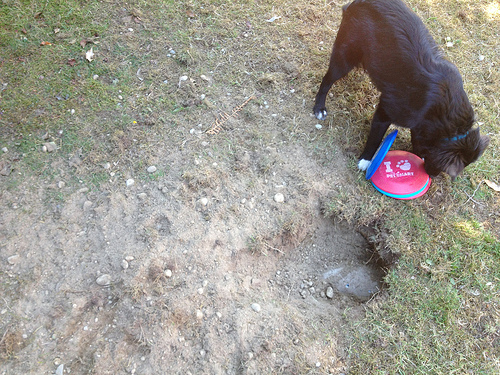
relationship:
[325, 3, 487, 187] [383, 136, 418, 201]
dog playing with kits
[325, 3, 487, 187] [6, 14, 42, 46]
dog on grass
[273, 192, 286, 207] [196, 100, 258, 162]
stone on ground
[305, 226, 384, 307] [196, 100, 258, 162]
hole in ground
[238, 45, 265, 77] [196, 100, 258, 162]
soil on ground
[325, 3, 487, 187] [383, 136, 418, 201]
dog biting kit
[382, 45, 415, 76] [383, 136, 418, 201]
black dog with kit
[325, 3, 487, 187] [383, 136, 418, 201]
dog playing with frisbees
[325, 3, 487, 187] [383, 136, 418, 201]
dog with frisbees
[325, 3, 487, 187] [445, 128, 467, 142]
dog with collar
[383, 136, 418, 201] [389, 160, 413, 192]
frisbees are blue and red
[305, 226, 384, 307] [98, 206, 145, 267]
hole in dirt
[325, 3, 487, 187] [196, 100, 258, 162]
dog has nose in ground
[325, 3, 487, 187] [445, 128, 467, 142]
dog wears collar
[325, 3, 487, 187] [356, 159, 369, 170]
dog has white feet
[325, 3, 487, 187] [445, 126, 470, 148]
dog collar blue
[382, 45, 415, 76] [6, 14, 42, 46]
black dog on grass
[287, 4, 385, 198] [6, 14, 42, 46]
frisbees near grass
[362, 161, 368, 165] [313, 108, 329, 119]
white on paw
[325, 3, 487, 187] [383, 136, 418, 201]
dog smelling frisbee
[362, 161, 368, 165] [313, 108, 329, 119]
white dog paw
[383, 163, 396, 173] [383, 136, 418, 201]
i on frisbee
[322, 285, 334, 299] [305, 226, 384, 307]
rock in a hole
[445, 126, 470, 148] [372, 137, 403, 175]
blue sideways frisbee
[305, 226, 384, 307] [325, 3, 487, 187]
hole near dog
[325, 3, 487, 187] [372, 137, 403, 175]
dog with frisbee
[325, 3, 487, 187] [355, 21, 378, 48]
dog with black fur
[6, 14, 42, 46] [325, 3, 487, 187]
grass near dog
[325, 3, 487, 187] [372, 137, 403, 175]
dog sniffing frisbee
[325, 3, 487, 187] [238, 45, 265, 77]
dog on soil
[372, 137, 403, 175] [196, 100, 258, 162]
frisbee on ground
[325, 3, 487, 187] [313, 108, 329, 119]
dog has white paw